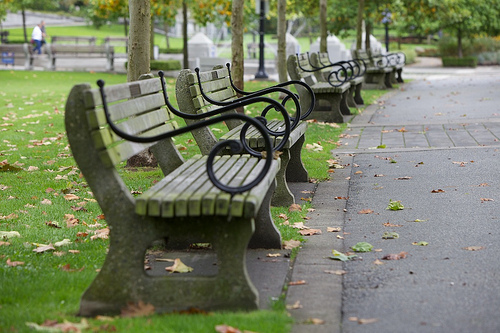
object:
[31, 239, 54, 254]
leaf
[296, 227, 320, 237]
leaf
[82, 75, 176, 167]
backrest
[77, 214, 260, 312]
bottom base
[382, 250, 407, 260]
leaf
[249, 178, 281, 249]
rest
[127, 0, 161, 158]
trunk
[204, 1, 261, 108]
tree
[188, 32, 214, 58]
fountain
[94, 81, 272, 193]
arm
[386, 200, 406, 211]
leaf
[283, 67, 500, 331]
trail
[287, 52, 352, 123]
bench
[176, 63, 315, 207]
bench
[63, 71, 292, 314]
benches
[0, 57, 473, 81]
path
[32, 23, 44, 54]
people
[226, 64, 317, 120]
arm rest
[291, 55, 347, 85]
arm rest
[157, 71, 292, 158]
arm rest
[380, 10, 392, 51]
lampost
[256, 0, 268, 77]
lampost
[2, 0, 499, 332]
park